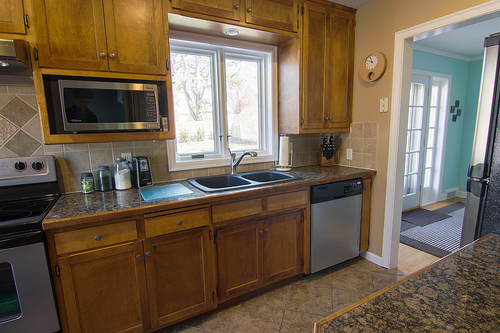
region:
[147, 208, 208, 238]
A drawer below the counter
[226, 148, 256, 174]
A fauce above the sink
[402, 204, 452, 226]
A mat by the door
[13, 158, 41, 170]
Knobs on the stove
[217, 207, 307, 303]
Cabinets below the sink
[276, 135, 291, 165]
Paper towels by the sink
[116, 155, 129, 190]
A container full of a spice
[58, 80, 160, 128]
A microwave in the kitchen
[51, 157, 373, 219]
A counter in the kitchen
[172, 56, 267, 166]
A window by the sink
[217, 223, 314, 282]
brown cabinets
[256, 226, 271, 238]
silver knobs on the cabinet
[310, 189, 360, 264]
a dishwasher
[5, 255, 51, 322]
an oven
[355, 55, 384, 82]
a clock on the wall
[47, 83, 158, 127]
a microwave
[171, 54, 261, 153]
a window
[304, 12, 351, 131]
long cabinets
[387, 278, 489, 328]
a marble counter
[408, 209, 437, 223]
a rug on the floor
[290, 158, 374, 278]
Stainless steel dishwsher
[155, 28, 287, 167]
Sunlight coming in the window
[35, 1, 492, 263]
Photo taken during the day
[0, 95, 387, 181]
Tile backsplash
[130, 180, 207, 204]
Cutting board on the counter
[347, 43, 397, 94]
Clock on the wall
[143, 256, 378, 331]
Kitchen floor made of tile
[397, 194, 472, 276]
Foyer floor is wood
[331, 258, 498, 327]
Granite counter tops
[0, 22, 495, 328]
Nobody in the photo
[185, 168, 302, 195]
the double sink in the kitchen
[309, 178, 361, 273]
the dishwasher under the counter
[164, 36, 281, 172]
the window above the kitchen sink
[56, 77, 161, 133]
the microwave in the cabinet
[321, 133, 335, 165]
the knife block on the counter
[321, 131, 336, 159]
the knives in the block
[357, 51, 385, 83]
the clock on the wall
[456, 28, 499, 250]
the refrigerator in the kitchen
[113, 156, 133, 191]
the jar on the counter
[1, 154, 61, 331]
the stove in the kitchen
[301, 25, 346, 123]
this is a shelf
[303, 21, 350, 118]
the shelf is closed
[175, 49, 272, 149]
this is the window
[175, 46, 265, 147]
the window is closed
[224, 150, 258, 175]
this is a tap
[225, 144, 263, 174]
the tap is closed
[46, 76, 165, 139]
this is a microwave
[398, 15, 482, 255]
the door is open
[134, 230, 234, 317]
the shelves are wooden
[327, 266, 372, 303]
the floor is tiled